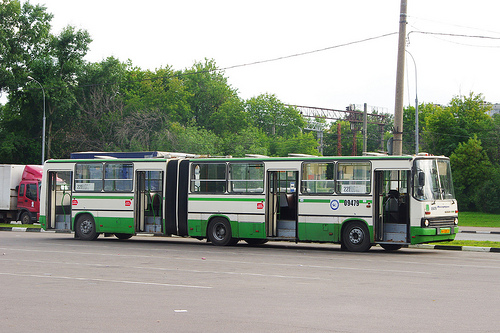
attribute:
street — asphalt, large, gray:
[3, 228, 500, 331]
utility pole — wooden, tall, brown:
[391, 2, 408, 153]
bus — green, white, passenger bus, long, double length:
[38, 154, 460, 253]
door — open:
[375, 168, 410, 237]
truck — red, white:
[0, 165, 43, 226]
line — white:
[0, 271, 211, 289]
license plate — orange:
[438, 228, 451, 236]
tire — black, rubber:
[74, 214, 98, 237]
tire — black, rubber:
[205, 215, 237, 246]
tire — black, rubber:
[340, 220, 371, 253]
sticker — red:
[71, 199, 78, 206]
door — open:
[265, 171, 297, 239]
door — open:
[135, 171, 164, 238]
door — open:
[48, 171, 74, 230]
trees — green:
[0, 2, 322, 162]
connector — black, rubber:
[161, 160, 189, 236]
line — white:
[2, 247, 417, 276]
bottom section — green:
[95, 217, 372, 243]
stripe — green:
[71, 195, 372, 204]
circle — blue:
[328, 199, 339, 210]